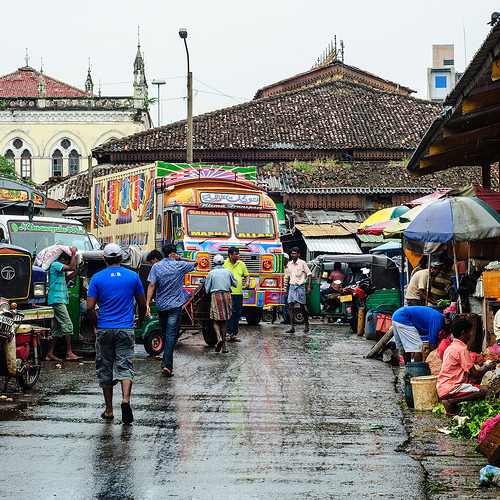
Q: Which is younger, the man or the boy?
A: The boy is younger than the man.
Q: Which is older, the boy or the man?
A: The man is older than the boy.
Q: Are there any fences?
A: No, there are no fences.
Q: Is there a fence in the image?
A: No, there are no fences.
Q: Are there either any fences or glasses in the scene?
A: No, there are no fences or glasses.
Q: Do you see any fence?
A: No, there are no fences.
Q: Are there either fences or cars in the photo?
A: No, there are no fences or cars.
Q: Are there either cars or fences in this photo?
A: No, there are no fences or cars.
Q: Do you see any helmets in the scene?
A: No, there are no helmets.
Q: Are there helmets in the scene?
A: No, there are no helmets.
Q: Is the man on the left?
A: Yes, the man is on the left of the image.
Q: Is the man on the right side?
A: No, the man is on the left of the image.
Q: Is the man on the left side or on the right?
A: The man is on the left of the image.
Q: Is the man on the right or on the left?
A: The man is on the left of the image.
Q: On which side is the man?
A: The man is on the left of the image.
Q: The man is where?
A: The man is on the road.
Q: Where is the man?
A: The man is on the road.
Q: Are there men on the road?
A: Yes, there is a man on the road.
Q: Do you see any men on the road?
A: Yes, there is a man on the road.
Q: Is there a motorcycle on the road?
A: No, there is a man on the road.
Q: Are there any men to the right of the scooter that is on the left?
A: Yes, there is a man to the right of the scooter.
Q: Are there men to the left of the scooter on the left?
A: No, the man is to the right of the scooter.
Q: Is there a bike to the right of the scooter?
A: No, there is a man to the right of the scooter.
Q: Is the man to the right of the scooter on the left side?
A: Yes, the man is to the right of the scooter.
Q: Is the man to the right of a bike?
A: No, the man is to the right of the scooter.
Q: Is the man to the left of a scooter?
A: No, the man is to the right of a scooter.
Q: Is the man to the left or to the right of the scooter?
A: The man is to the right of the scooter.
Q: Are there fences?
A: No, there are no fences.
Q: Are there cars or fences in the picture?
A: No, there are no fences or cars.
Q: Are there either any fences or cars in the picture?
A: No, there are no fences or cars.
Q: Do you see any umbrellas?
A: Yes, there is an umbrella.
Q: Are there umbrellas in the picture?
A: Yes, there is an umbrella.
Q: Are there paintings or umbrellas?
A: Yes, there is an umbrella.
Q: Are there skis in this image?
A: No, there are no skis.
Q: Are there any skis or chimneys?
A: No, there are no skis or chimneys.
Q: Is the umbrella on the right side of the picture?
A: Yes, the umbrella is on the right of the image.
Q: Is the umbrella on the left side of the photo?
A: No, the umbrella is on the right of the image.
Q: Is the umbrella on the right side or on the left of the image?
A: The umbrella is on the right of the image.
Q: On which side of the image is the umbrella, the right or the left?
A: The umbrella is on the right of the image.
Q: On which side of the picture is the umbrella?
A: The umbrella is on the right of the image.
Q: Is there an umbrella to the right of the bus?
A: Yes, there is an umbrella to the right of the bus.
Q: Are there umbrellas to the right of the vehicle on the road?
A: Yes, there is an umbrella to the right of the bus.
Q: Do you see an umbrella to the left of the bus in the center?
A: No, the umbrella is to the right of the bus.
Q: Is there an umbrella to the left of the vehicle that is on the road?
A: No, the umbrella is to the right of the bus.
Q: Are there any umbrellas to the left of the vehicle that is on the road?
A: No, the umbrella is to the right of the bus.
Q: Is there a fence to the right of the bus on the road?
A: No, there is an umbrella to the right of the bus.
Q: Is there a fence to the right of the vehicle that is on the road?
A: No, there is an umbrella to the right of the bus.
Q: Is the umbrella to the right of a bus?
A: Yes, the umbrella is to the right of a bus.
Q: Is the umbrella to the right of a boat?
A: No, the umbrella is to the right of a bus.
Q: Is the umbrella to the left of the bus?
A: No, the umbrella is to the right of the bus.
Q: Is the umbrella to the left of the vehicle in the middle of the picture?
A: No, the umbrella is to the right of the bus.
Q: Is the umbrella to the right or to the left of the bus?
A: The umbrella is to the right of the bus.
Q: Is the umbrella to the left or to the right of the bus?
A: The umbrella is to the right of the bus.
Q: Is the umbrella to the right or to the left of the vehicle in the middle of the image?
A: The umbrella is to the right of the bus.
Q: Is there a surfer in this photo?
A: No, there are no surfers.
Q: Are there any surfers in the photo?
A: No, there are no surfers.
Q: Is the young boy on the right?
A: Yes, the boy is on the right of the image.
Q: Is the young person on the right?
A: Yes, the boy is on the right of the image.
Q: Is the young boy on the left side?
A: No, the boy is on the right of the image.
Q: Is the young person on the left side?
A: No, the boy is on the right of the image.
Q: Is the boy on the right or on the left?
A: The boy is on the right of the image.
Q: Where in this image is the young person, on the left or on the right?
A: The boy is on the right of the image.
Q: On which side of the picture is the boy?
A: The boy is on the right of the image.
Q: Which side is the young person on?
A: The boy is on the right of the image.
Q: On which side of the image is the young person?
A: The boy is on the right of the image.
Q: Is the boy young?
A: Yes, the boy is young.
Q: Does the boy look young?
A: Yes, the boy is young.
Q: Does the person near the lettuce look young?
A: Yes, the boy is young.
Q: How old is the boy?
A: The boy is young.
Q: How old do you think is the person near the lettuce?
A: The boy is young.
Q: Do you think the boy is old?
A: No, the boy is young.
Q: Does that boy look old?
A: No, the boy is young.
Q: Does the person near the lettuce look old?
A: No, the boy is young.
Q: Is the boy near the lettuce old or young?
A: The boy is young.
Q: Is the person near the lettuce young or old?
A: The boy is young.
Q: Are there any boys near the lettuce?
A: Yes, there is a boy near the lettuce.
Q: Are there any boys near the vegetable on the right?
A: Yes, there is a boy near the lettuce.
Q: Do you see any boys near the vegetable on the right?
A: Yes, there is a boy near the lettuce.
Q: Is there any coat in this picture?
A: No, there are no coats.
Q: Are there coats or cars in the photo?
A: No, there are no coats or cars.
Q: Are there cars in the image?
A: No, there are no cars.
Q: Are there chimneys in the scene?
A: No, there are no chimneys.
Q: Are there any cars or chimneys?
A: No, there are no chimneys or cars.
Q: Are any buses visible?
A: Yes, there is a bus.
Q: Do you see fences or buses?
A: Yes, there is a bus.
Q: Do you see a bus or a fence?
A: Yes, there is a bus.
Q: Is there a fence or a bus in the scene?
A: Yes, there is a bus.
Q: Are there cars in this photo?
A: No, there are no cars.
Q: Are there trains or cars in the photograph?
A: No, there are no cars or trains.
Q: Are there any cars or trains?
A: No, there are no cars or trains.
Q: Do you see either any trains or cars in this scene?
A: No, there are no cars or trains.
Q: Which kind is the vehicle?
A: The vehicle is a bus.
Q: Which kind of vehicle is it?
A: The vehicle is a bus.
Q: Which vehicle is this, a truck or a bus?
A: This is a bus.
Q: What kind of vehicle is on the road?
A: The vehicle is a bus.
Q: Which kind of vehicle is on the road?
A: The vehicle is a bus.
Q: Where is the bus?
A: The bus is on the road.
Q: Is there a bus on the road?
A: Yes, there is a bus on the road.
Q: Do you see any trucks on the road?
A: No, there is a bus on the road.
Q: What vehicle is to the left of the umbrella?
A: The vehicle is a bus.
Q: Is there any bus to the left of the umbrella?
A: Yes, there is a bus to the left of the umbrella.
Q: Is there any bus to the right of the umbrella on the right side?
A: No, the bus is to the left of the umbrella.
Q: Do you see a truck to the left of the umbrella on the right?
A: No, there is a bus to the left of the umbrella.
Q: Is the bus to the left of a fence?
A: No, the bus is to the left of the umbrella.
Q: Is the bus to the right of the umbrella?
A: No, the bus is to the left of the umbrella.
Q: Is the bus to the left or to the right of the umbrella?
A: The bus is to the left of the umbrella.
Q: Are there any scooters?
A: Yes, there is a scooter.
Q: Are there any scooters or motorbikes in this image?
A: Yes, there is a scooter.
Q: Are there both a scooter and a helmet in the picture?
A: No, there is a scooter but no helmets.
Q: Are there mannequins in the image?
A: No, there are no mannequins.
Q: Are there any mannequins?
A: No, there are no mannequins.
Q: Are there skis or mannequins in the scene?
A: No, there are no mannequins or skis.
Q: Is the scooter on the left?
A: Yes, the scooter is on the left of the image.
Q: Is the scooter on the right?
A: No, the scooter is on the left of the image.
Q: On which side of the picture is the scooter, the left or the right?
A: The scooter is on the left of the image.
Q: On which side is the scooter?
A: The scooter is on the left of the image.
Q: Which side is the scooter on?
A: The scooter is on the left of the image.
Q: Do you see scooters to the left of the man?
A: Yes, there is a scooter to the left of the man.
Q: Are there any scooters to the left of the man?
A: Yes, there is a scooter to the left of the man.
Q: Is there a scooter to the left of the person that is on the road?
A: Yes, there is a scooter to the left of the man.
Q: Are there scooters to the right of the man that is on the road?
A: No, the scooter is to the left of the man.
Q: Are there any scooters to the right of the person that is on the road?
A: No, the scooter is to the left of the man.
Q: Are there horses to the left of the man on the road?
A: No, there is a scooter to the left of the man.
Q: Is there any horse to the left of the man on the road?
A: No, there is a scooter to the left of the man.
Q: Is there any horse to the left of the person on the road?
A: No, there is a scooter to the left of the man.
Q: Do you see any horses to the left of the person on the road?
A: No, there is a scooter to the left of the man.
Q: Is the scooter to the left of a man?
A: Yes, the scooter is to the left of a man.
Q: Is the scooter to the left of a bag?
A: No, the scooter is to the left of a man.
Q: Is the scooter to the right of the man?
A: No, the scooter is to the left of the man.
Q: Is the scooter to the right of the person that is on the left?
A: No, the scooter is to the left of the man.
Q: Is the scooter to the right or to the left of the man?
A: The scooter is to the left of the man.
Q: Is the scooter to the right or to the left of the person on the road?
A: The scooter is to the left of the man.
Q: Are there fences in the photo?
A: No, there are no fences.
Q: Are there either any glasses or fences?
A: No, there are no fences or glasses.